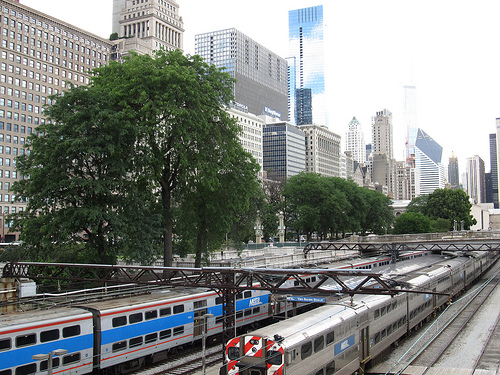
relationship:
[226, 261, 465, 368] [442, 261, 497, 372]
train on tracks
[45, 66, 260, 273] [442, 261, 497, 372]
tree near tracks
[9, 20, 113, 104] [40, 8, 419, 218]
windows on buildings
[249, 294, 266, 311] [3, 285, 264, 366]
logo on cars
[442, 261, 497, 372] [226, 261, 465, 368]
tracks near train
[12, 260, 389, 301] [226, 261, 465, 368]
supports above train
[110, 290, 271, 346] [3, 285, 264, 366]
line on train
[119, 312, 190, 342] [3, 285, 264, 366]
windows on train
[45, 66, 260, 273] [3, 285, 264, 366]
tree near cars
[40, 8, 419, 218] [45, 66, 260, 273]
buildings near tree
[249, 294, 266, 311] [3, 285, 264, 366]
logo on train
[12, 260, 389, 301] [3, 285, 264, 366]
supports over cars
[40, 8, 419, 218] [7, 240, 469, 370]
buildings near trains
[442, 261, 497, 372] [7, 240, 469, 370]
tracks have trains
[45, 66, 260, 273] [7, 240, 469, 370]
tree near trains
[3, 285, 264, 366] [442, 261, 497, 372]
cars on tracks